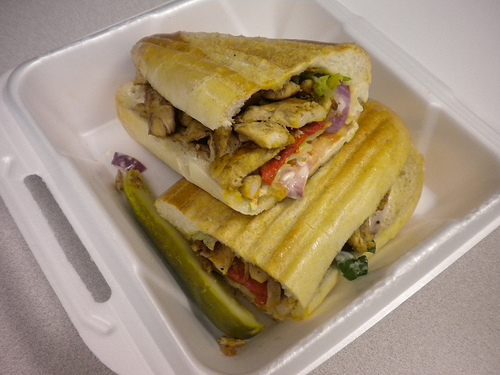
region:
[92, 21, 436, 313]
sandwich that has been cut in half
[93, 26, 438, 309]
half of a sandwich laying on top of the other half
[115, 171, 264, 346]
long green pickle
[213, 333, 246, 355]
crumb from the sandwich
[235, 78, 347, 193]
food sticking out of the bread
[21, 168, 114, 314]
long cutout in the box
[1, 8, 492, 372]
food sitting in a white styrofoam box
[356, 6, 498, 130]
lid of the box is hanging open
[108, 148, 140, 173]
bit of purple food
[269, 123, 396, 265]
raised lines on the bread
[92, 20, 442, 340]
two sandwiches on a foam container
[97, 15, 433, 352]
sandwiches of meat and vegetables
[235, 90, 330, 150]
pieces of white meat inside sandwich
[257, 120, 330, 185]
red pepper in the sandwich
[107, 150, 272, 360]
pickle on side a sandwich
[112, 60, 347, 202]
pieces of meat inside bread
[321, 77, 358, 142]
onion inside of sandwich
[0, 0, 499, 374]
white foam container is open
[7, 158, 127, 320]
a hole in a foam box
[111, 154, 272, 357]
pickle is green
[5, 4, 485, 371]
white styrofoam container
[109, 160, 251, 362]
a dill pickle spear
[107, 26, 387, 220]
top half of the sandwich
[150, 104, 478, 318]
the bottom half of the sandwich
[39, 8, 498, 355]
a sandwich in a styrofoam container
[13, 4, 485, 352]
sandwich in a to-go box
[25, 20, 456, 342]
a sandwich with a pickle on the side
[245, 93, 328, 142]
pieces of chicken breast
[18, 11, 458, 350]
a chicken sandwich in a box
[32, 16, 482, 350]
a chicken sub with a slice of pickle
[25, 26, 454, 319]
sandwich in a styrofoam box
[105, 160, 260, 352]
pickle next to the sandwich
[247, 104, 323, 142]
chicken on the sandwich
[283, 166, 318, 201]
onion on the sandwich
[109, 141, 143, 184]
piece of onion in the box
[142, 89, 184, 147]
chicken in the sandwich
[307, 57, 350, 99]
lettuce in the sandwich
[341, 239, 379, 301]
lettuce in the sandwich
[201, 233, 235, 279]
chicken in the sandwich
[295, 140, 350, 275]
grooves in the bread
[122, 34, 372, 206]
A chicken sandwich on Italian bread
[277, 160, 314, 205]
a cooked red onion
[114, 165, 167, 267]
a green pickle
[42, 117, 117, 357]
a white styrofoam container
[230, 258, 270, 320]
a cooked red pepper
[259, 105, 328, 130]
grilled chicken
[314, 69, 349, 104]
a piece of lettuce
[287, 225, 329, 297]
a toasted italian bread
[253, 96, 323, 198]
grilled chicken, red pepper and a red onion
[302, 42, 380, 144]
bread, grilled chicken, lettuce, red pepper and red onion